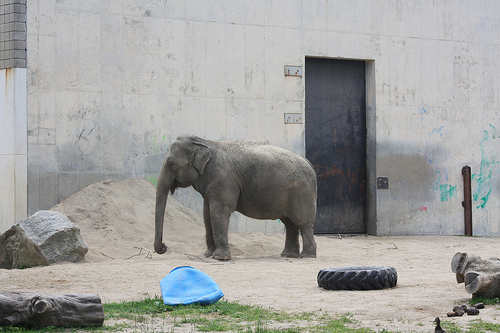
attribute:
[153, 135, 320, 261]
elephant — grey, large, gray, standing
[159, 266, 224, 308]
item — blue colored, flat, blue, squished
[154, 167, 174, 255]
trunk — long, straight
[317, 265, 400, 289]
tire — large, rubber, old, black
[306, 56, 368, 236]
door — black, tall, metal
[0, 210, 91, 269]
stone — large, grey, gray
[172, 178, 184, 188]
mouth — opened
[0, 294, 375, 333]
patch — grass, small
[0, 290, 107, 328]
log — gray, of a tree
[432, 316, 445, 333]
duckling — black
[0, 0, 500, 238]
wall — gray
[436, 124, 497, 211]
graffiti — green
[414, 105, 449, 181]
stuff — blue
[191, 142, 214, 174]
ear — big